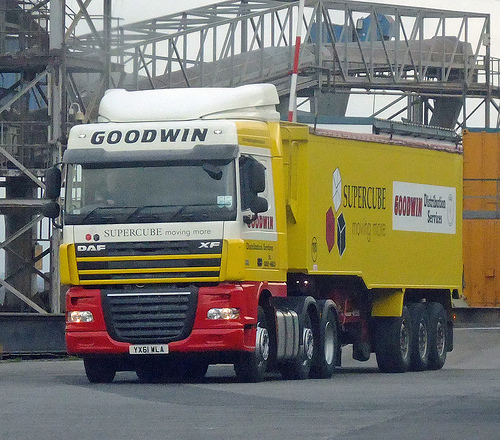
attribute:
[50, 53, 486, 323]
truck — yellow, white, black, top, large, rectangular, big, light, print, side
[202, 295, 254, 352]
part — red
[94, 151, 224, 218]
glass — clear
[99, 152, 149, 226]
man — driving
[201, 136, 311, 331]
door — yellow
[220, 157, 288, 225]
mirror — truck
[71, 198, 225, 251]
wiper — black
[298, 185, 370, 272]
logo — company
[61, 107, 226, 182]
letter — black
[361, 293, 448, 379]
tire — black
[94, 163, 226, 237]
windshield — truck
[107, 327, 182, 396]
plate — number